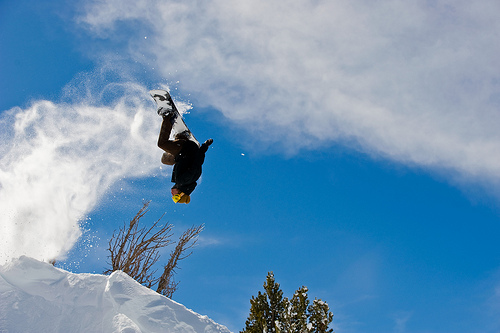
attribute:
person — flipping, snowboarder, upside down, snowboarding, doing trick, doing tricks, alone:
[152, 93, 214, 204]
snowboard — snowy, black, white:
[147, 87, 200, 148]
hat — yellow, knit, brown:
[177, 194, 190, 204]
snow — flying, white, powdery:
[1, 36, 246, 274]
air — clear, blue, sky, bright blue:
[1, 0, 499, 332]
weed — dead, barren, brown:
[157, 224, 207, 300]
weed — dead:
[103, 196, 176, 288]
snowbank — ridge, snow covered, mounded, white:
[0, 255, 234, 333]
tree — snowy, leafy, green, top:
[240, 271, 333, 332]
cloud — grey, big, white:
[67, 1, 500, 202]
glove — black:
[204, 138, 214, 147]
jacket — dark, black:
[171, 139, 208, 194]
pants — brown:
[157, 115, 189, 166]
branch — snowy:
[308, 298, 335, 332]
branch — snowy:
[290, 286, 310, 333]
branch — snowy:
[263, 271, 291, 333]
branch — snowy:
[239, 290, 270, 333]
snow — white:
[161, 107, 169, 118]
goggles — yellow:
[171, 192, 184, 203]